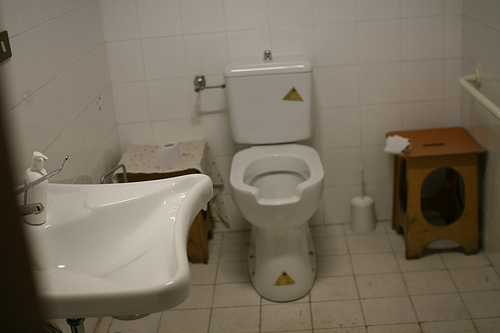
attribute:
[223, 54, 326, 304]
toilet — white, lidless, seatless, broken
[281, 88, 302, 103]
sticker — yellow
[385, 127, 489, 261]
stool — wooden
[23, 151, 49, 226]
dispenser — hand soap, plastic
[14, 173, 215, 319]
sink — porcelain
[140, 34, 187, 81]
tile — white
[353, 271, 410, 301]
floor tile — white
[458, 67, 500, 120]
handrail — hanging, cream, white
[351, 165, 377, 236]
toilet cleaner — white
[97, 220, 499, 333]
floor — dirty, tiled, ceramic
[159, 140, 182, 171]
toilet paper — rolled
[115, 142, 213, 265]
stool — wooden, brown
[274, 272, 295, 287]
sticker — yellow